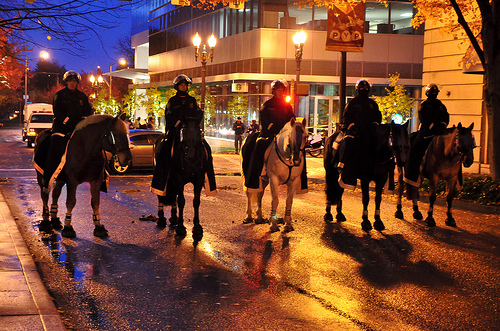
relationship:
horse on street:
[238, 115, 310, 233] [85, 112, 455, 311]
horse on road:
[238, 115, 310, 233] [1, 125, 499, 327]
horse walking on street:
[39, 122, 136, 213] [47, 209, 463, 299]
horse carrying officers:
[31, 112, 135, 238] [49, 60, 96, 137]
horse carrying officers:
[238, 115, 310, 233] [157, 66, 209, 142]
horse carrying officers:
[238, 115, 310, 233] [244, 75, 306, 145]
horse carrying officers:
[238, 115, 310, 233] [334, 69, 388, 146]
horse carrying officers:
[238, 115, 310, 233] [416, 81, 456, 138]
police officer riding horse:
[413, 78, 446, 172] [392, 119, 476, 226]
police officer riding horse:
[344, 78, 379, 185] [318, 118, 399, 229]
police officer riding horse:
[252, 78, 293, 180] [234, 111, 309, 234]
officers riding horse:
[158, 73, 213, 158] [148, 118, 215, 228]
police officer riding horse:
[48, 70, 91, 175] [31, 111, 135, 237]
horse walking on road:
[31, 112, 135, 238] [1, 125, 499, 327]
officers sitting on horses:
[16, 61, 483, 151] [30, 121, 478, 233]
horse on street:
[238, 115, 310, 233] [10, 173, 495, 327]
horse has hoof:
[238, 115, 310, 233] [60, 224, 77, 237]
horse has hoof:
[31, 112, 135, 238] [174, 221, 187, 236]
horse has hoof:
[238, 115, 310, 233] [267, 217, 283, 234]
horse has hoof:
[238, 115, 310, 233] [357, 218, 373, 233]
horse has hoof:
[238, 115, 310, 233] [424, 215, 438, 229]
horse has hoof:
[238, 115, 310, 233] [192, 224, 204, 238]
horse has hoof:
[31, 112, 135, 238] [173, 220, 188, 240]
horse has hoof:
[395, 114, 478, 230] [444, 211, 458, 228]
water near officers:
[50, 237, 90, 287] [158, 73, 213, 158]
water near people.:
[66, 270, 88, 284] [414, 80, 452, 130]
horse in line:
[238, 115, 310, 233] [15, 112, 489, 246]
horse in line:
[395, 114, 478, 230] [15, 112, 489, 246]